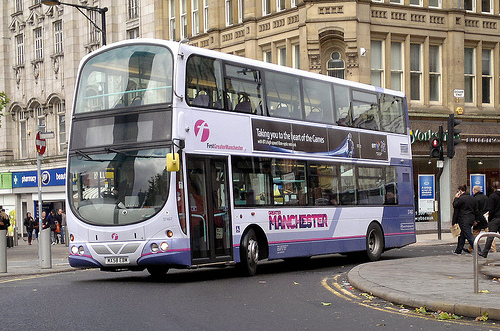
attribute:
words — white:
[256, 126, 329, 148]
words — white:
[265, 208, 326, 228]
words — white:
[407, 123, 457, 142]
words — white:
[419, 171, 436, 211]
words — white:
[19, 174, 38, 183]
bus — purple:
[62, 35, 417, 275]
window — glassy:
[230, 151, 271, 207]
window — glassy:
[302, 79, 331, 124]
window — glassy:
[255, 72, 302, 113]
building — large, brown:
[179, 10, 498, 138]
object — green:
[80, 84, 169, 99]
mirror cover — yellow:
[166, 151, 181, 173]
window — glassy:
[366, 84, 411, 141]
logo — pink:
[190, 117, 214, 148]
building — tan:
[156, 0, 497, 118]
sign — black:
[244, 113, 404, 170]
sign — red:
[35, 126, 52, 160]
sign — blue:
[459, 172, 491, 198]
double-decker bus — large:
[59, 39, 417, 263]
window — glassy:
[327, 80, 356, 128]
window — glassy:
[352, 85, 381, 128]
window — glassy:
[272, 163, 313, 212]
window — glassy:
[305, 164, 339, 210]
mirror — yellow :
[163, 155, 185, 183]